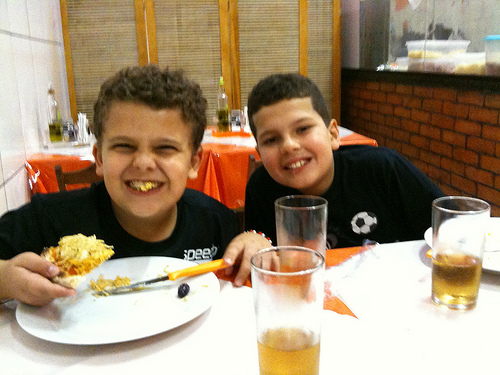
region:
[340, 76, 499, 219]
Two boys sitting at the table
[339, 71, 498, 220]
Brown bricks on a wall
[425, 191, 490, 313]
A beverage in a glass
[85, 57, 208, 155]
Brown curly hair on boy's head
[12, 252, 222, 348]
A white round plate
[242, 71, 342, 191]
A boy is smiling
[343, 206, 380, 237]
Soccer ball picture on black shirt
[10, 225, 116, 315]
Food in a hand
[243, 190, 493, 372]
Three glasses on the table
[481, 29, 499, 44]
Blue lid on a container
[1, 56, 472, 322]
two kids sitting at a table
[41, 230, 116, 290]
slice of pizza in the kid's hand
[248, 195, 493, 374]
three glasses on the table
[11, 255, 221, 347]
a round white plate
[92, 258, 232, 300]
a knife with a yellow handle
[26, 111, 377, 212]
long table with orange tablecloth in the background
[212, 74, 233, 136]
a bottle of olive oil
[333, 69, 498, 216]
a brick wall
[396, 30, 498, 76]
plastic containers stacked in the window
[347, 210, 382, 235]
soccer ball on the kid's shirt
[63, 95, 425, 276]
two boys at table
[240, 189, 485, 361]
clear glasses on table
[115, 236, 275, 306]
boy is holding knife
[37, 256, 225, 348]
white plate on table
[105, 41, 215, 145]
boy has curly hair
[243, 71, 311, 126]
boy has brown hair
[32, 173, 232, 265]
boy has black shirt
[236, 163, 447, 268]
boy has dark blue shirt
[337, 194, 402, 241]
soccer ball on shirt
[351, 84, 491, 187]
bricks on wall behind boys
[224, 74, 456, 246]
Boy sitting at table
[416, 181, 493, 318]
Glass on the table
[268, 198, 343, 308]
Glass on the table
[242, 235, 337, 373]
Glass on the table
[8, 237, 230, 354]
Plate on the table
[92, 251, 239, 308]
Knife on the plate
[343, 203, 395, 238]
Soccer ball on shirt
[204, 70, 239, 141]
Bottle on the table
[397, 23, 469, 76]
Container on the table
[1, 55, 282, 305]
Boy wearing a black shirt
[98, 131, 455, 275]
these are two people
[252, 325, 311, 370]
this is orange juice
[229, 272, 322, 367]
this is a tall glass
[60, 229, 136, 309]
this is a piece of food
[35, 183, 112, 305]
this is a shirt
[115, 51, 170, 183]
this is a head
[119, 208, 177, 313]
this is a utensil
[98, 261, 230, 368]
this is a knife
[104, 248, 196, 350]
the knife is orange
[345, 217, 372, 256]
this is a ball